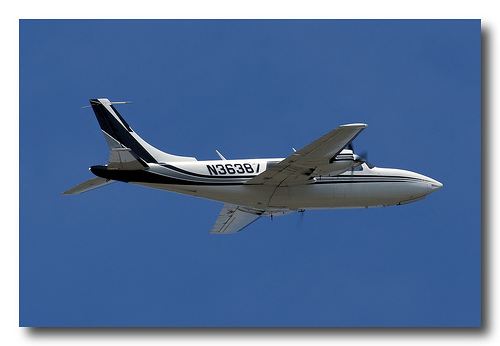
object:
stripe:
[127, 169, 245, 185]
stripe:
[157, 162, 258, 179]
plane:
[60, 97, 443, 235]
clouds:
[22, 19, 308, 81]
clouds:
[107, 273, 232, 322]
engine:
[298, 209, 305, 216]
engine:
[333, 142, 374, 175]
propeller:
[348, 142, 368, 171]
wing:
[244, 122, 368, 186]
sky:
[21, 22, 483, 325]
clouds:
[393, 85, 479, 137]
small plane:
[61, 97, 443, 235]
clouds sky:
[390, 238, 480, 278]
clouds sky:
[343, 47, 476, 98]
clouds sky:
[18, 89, 62, 150]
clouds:
[152, 73, 221, 103]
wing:
[210, 202, 263, 234]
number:
[206, 163, 260, 175]